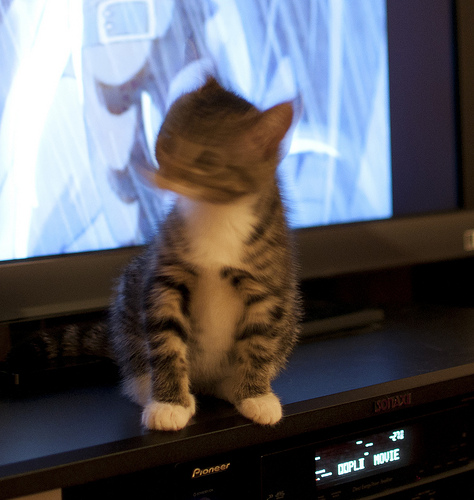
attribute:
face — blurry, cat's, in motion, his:
[151, 73, 295, 203]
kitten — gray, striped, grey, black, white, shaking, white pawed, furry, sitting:
[112, 73, 301, 431]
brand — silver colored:
[190, 462, 231, 477]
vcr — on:
[62, 391, 473, 500]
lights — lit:
[313, 428, 403, 482]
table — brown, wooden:
[2, 303, 473, 499]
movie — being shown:
[1, 0, 391, 259]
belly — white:
[177, 193, 260, 380]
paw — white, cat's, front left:
[141, 392, 196, 430]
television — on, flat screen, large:
[0, 0, 473, 337]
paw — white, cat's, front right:
[235, 392, 282, 426]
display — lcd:
[312, 424, 414, 486]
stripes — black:
[143, 253, 200, 369]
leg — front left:
[140, 257, 199, 430]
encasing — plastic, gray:
[1, 0, 473, 323]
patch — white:
[177, 193, 265, 267]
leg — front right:
[218, 267, 285, 424]